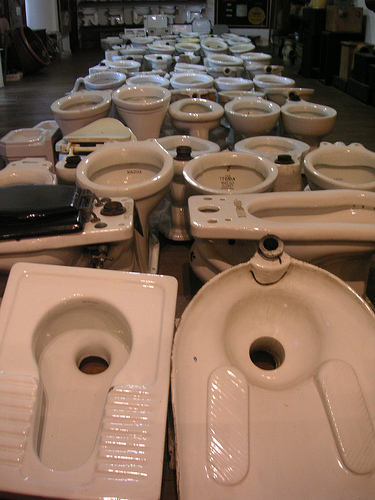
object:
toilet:
[0, 183, 134, 274]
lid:
[0, 184, 93, 241]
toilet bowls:
[76, 4, 161, 28]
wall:
[74, 4, 219, 55]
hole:
[75, 342, 111, 376]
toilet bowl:
[0, 27, 375, 500]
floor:
[152, 207, 206, 318]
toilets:
[0, 29, 375, 500]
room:
[0, 0, 375, 499]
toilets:
[74, 4, 207, 28]